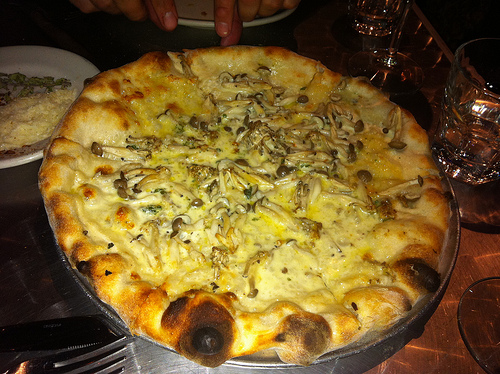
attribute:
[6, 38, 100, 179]
plate — round, white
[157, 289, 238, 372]
crust — burnt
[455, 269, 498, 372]
plate — clear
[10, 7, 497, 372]
table — one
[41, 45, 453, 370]
pizza — cheese, large 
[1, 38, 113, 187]
plate — white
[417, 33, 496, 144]
glass — clear, drinking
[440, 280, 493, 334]
plate — clear, glass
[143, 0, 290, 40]
plate — round, white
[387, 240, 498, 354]
table — brown, wooden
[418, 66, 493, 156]
glass — clear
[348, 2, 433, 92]
glass — one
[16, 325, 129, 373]
fork — silver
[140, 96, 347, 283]
cheese — melted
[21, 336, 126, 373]
utensil — eating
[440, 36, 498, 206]
glass — drinking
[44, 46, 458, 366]
crust — nicely browned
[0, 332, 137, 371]
silver fork — silver 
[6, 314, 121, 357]
silver knife — silver 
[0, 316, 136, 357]
silver knife — silver 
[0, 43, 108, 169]
white plate — round , white 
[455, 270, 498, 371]
round plate — clear , round 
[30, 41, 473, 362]
silver pan — large , silver 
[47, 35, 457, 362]
round food — round 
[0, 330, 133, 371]
fork end — silver 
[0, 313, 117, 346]
butter knife — dark 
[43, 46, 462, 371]
tray — Silver 